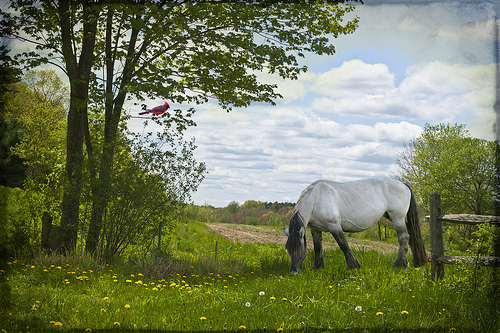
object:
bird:
[139, 101, 173, 115]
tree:
[86, 1, 361, 263]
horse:
[282, 175, 423, 275]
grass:
[1, 217, 499, 331]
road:
[206, 222, 398, 254]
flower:
[198, 312, 207, 320]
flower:
[53, 319, 62, 326]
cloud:
[306, 58, 397, 95]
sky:
[1, 1, 499, 202]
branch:
[117, 113, 168, 121]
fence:
[422, 189, 500, 283]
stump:
[36, 210, 63, 252]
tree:
[449, 133, 497, 239]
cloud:
[308, 95, 444, 119]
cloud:
[211, 158, 278, 171]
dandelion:
[257, 289, 266, 298]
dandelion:
[269, 295, 276, 301]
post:
[427, 191, 446, 280]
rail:
[424, 212, 499, 225]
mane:
[287, 212, 301, 250]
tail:
[406, 180, 428, 266]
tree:
[2, 1, 105, 250]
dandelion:
[124, 277, 133, 283]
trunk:
[84, 85, 124, 258]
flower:
[123, 303, 131, 309]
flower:
[374, 307, 383, 318]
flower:
[400, 307, 409, 316]